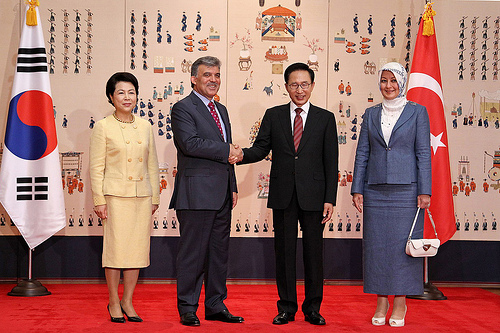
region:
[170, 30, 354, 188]
men are shaking hands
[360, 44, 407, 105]
woman wearing a covering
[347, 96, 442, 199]
woman wearing blue jacket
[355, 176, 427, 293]
woman wearing blue skirt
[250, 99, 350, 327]
man's suit is black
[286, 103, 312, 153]
man's tie is red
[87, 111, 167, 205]
woman's jacket is yellow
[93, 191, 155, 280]
woman's skirt is yellow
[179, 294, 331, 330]
men's shoes are black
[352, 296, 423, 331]
woman's shoes are white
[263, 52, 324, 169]
a man wearing glasses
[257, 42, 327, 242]
a man wearing a black suit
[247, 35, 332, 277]
a man with brown hair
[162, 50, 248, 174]
a man with grey hair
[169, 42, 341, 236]
two people shaking hands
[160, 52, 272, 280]
a man wearing a blue suit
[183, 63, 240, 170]
a man wearing a red tie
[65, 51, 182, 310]
a woman wearing a yellow outfit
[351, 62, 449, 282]
a woman holding a white purse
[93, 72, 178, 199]
a woman wearing a necklace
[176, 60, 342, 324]
Two men shaking hands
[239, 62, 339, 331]
Man in black suit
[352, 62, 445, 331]
Woman wearing grey suit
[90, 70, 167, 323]
Woman wearing beige suit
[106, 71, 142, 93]
Thick very black hair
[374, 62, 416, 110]
Woman wearing a scarf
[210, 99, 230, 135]
Red and white tie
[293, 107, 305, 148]
Red and grey tie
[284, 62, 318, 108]
Man wearing clear glasses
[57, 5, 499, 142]
Painted wall behind people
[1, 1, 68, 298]
flag on pole in stand on left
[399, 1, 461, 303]
flag on pole in stand on right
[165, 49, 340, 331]
two men shaking hands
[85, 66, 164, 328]
woman in two-piece light yellow skirt suit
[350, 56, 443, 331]
woman in three-piece denim blue suit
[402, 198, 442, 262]
white purse held by woman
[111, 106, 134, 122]
necklace on woman in yellow suit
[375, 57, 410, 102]
head scarf on woman in denim suit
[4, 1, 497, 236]
hieroglyphs on wall behind people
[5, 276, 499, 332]
bright red carpet on ground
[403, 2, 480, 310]
flag with a white star on it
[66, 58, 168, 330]
woman in a yellow outfit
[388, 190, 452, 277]
a small white purse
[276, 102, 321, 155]
a red and brown tie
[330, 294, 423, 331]
a pair of white heels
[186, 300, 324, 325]
two pairs of black shiny shoes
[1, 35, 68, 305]
a flag with a brown and red circle on it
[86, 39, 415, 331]
four people standing for a picture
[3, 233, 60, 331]
bottom of a flag pole holder